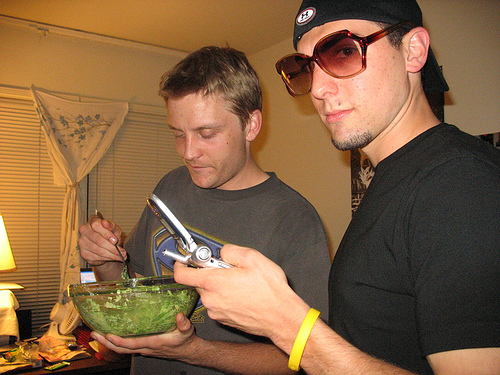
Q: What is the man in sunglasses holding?
A: A cellphone.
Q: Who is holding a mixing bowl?
A: The man with the blond hair.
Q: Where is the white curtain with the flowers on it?
A: Hanging on the window.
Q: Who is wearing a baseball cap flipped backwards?
A: The man in the sunglasses.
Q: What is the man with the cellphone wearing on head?
A: A baseball cap.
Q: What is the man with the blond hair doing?
A: Stirring green stuff in a bowl.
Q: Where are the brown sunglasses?
A: On a man's face.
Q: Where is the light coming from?
A: A lamp on the table.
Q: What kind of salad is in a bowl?
A: Avocado salad.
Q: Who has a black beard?
A: A young man.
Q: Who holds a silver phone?
A: A man.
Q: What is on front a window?
A: A curtain.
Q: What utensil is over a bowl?
A: A spoon.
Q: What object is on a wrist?
A: A band.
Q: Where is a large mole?
A: Near the mouth.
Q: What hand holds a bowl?
A: A left hand.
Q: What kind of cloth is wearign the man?
A: A tee shirt.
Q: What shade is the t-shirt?
A: Grey.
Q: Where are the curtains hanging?
A: On the windows.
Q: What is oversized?
A: Sunglasses.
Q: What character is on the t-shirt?
A: Superman.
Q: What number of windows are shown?
A: Two.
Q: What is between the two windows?
A: A curtain.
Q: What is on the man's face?
A: Sunglasses.